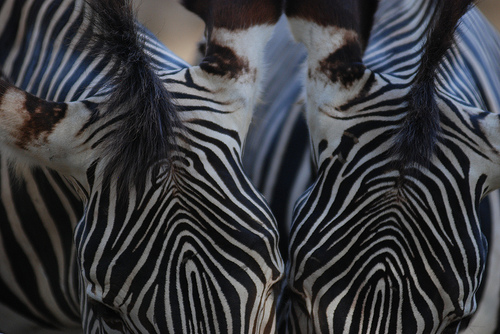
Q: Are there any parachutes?
A: No, there are no parachutes.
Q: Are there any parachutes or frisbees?
A: No, there are no parachutes or frisbees.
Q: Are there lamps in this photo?
A: No, there are no lamps.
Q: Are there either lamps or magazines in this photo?
A: No, there are no lamps or magazines.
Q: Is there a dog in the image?
A: No, there are no dogs.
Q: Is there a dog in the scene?
A: No, there are no dogs.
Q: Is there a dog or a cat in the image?
A: No, there are no dogs or cats.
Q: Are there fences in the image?
A: No, there are no fences.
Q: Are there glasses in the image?
A: No, there are no glasses.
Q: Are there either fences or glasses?
A: No, there are no glasses or fences.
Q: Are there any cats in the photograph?
A: No, there are no cats.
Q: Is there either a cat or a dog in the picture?
A: No, there are no cats or dogs.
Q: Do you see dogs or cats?
A: No, there are no cats or dogs.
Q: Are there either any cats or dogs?
A: No, there are no cats or dogs.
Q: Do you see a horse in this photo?
A: No, there are no horses.